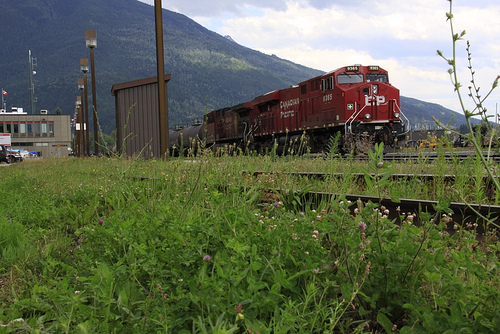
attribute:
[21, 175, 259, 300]
grass — green, long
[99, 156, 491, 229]
tracks — train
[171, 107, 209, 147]
truck — tanker